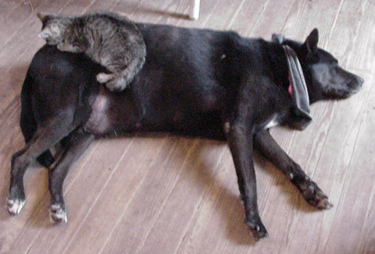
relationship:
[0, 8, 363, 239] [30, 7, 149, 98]
dog with cat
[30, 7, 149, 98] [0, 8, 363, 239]
cat sleeps dog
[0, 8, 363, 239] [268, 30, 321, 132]
dog wears bandana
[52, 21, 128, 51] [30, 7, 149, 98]
grey sleeping cat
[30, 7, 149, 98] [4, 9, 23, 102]
cat lies floor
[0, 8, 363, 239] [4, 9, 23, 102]
dog lies floor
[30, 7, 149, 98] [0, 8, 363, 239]
cat and dog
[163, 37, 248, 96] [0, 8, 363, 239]
black sleepy dog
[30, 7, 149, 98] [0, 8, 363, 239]
cat pillow dog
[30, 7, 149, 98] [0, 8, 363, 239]
cat laying dog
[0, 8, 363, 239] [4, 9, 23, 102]
dog on floor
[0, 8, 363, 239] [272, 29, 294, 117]
dog something neck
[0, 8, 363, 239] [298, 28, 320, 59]
dog ear ear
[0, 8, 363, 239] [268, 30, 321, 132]
dog black bandana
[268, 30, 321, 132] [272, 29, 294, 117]
bandana on neck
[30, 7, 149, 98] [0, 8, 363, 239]
kitten on dog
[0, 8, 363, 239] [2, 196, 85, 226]
dog white paws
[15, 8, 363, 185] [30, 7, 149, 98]
dog likes kitten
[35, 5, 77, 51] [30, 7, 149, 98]
head of cat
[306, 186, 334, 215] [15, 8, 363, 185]
paw of dog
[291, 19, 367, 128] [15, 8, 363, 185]
head of dog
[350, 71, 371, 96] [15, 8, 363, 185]
nose of dog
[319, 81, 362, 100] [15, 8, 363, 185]
mouth of dog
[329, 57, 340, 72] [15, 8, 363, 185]
eye of dog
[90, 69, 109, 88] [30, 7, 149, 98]
paw of cat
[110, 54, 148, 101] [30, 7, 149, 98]
tail of cat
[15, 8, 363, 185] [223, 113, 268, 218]
dog black leg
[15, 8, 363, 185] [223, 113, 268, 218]
dog has leg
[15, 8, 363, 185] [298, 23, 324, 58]
dog has ear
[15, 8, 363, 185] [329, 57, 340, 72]
dog has eye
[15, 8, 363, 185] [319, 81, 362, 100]
dog has mouth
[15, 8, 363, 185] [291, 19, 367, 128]
dog has head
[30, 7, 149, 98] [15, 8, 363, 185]
cat on dog